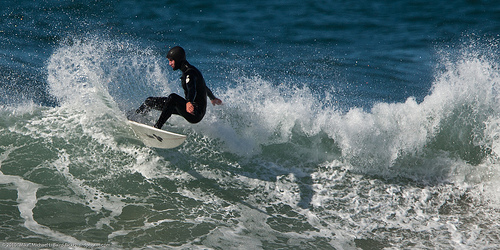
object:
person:
[120, 42, 240, 150]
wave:
[1, 32, 498, 248]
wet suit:
[148, 63, 240, 140]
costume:
[179, 69, 192, 83]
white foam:
[38, 35, 498, 188]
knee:
[167, 86, 178, 95]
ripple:
[289, 16, 494, 45]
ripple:
[169, 42, 291, 71]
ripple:
[70, 14, 252, 56]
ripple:
[1, 9, 242, 31]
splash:
[36, 27, 499, 166]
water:
[7, 0, 498, 248]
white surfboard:
[123, 117, 188, 148]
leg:
[154, 92, 192, 129]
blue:
[7, 8, 498, 45]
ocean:
[8, 9, 492, 249]